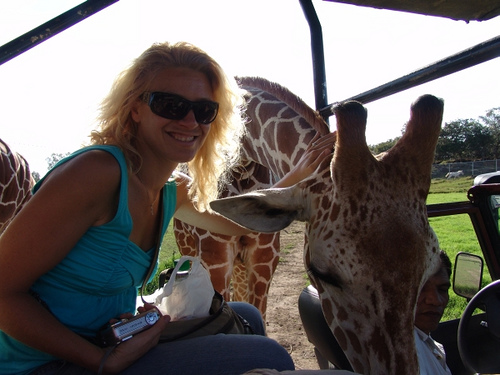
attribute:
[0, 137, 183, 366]
shirt — blue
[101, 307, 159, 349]
camera — silver, pink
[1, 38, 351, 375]
woman — smiling, sitting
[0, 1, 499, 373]
vehicle — open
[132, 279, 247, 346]
bag — in womans lap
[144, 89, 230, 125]
sunglasses — black, dark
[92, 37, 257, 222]
hair — blonde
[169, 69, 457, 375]
giraffe — brown, friendly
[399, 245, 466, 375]
man — sitting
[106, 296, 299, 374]
jeans — blue